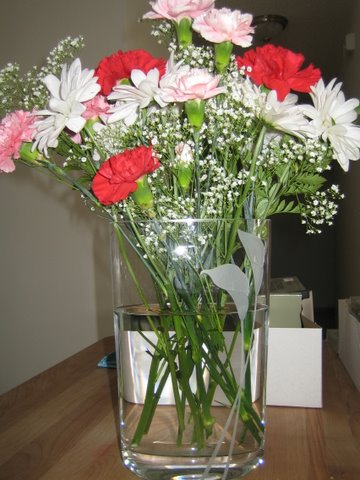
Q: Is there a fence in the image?
A: No, there are no fences.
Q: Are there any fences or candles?
A: No, there are no fences or candles.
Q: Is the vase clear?
A: Yes, the vase is clear.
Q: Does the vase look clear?
A: Yes, the vase is clear.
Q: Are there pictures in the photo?
A: No, there are no pictures.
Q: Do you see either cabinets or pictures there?
A: No, there are no pictures or cabinets.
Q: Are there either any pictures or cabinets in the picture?
A: No, there are no pictures or cabinets.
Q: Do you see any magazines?
A: No, there are no magazines.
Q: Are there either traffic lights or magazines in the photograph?
A: No, there are no magazines or traffic lights.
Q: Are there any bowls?
A: No, there are no bowls.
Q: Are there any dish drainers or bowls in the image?
A: No, there are no bowls or dish drainers.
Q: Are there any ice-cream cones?
A: No, there are no ice-cream cones.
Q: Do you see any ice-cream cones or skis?
A: No, there are no ice-cream cones or skis.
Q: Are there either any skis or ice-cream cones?
A: No, there are no ice-cream cones or skis.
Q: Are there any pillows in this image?
A: No, there are no pillows.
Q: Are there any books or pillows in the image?
A: No, there are no pillows or books.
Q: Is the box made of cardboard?
A: Yes, the box is made of cardboard.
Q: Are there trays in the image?
A: No, there are no trays.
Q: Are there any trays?
A: No, there are no trays.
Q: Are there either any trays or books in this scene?
A: No, there are no trays or books.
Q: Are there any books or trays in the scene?
A: No, there are no trays or books.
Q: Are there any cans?
A: No, there are no cans.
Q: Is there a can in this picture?
A: No, there are no cans.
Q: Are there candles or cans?
A: No, there are no cans or candles.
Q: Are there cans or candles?
A: No, there are no cans or candles.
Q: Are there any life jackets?
A: No, there are no life jackets.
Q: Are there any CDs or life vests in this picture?
A: No, there are no life vests or cds.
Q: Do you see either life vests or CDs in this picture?
A: No, there are no life vests or cds.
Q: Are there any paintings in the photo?
A: No, there are no paintings.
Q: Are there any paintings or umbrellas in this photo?
A: No, there are no paintings or umbrellas.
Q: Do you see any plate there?
A: No, there are no plates.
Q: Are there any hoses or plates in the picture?
A: No, there are no plates or hoses.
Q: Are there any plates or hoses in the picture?
A: No, there are no plates or hoses.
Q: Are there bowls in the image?
A: No, there are no bowls.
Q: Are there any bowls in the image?
A: No, there are no bowls.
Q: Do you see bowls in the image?
A: No, there are no bowls.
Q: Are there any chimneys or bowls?
A: No, there are no bowls or chimneys.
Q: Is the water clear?
A: Yes, the water is clear.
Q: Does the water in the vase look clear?
A: Yes, the water is clear.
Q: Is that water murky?
A: No, the water is clear.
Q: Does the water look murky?
A: No, the water is clear.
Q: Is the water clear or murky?
A: The water is clear.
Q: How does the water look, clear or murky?
A: The water is clear.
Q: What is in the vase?
A: The water is in the vase.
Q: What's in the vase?
A: The water is in the vase.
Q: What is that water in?
A: The water is in the vase.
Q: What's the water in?
A: The water is in the vase.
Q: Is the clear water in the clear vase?
A: Yes, the water is in the vase.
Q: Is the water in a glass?
A: No, the water is in the vase.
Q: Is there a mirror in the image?
A: No, there are no mirrors.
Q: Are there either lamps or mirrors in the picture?
A: No, there are no mirrors or lamps.